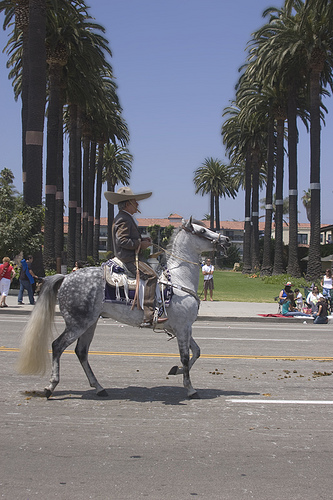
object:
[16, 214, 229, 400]
horse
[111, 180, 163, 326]
man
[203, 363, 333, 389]
dirt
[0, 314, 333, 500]
street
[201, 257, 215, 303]
people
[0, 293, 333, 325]
sidewalk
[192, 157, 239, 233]
trees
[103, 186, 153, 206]
hat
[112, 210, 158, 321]
costume